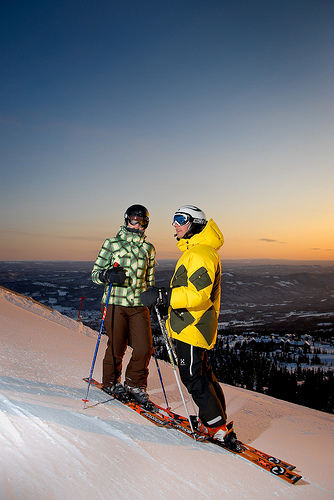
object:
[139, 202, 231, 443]
people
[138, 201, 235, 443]
man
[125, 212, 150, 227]
goggles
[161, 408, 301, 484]
skis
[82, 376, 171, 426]
skis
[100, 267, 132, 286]
glove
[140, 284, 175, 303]
glove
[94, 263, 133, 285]
hand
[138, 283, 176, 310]
hand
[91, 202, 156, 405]
people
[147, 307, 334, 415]
trees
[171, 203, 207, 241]
helmet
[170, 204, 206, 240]
head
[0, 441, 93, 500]
ground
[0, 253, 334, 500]
valley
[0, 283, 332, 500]
slope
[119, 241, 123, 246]
green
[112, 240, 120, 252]
white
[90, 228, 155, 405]
outfit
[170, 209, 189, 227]
goggles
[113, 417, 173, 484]
groove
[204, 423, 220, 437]
shoe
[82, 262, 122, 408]
ski pole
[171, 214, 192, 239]
face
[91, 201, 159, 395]
man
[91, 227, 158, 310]
coat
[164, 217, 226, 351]
coat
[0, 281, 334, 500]
mountain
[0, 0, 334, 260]
sky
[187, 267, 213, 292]
pocket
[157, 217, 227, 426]
outfit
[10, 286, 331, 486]
snow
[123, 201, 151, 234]
helmet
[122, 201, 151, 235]
head